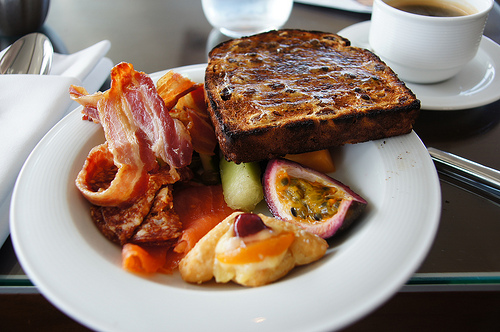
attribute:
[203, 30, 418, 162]
topping — fresh, burnt, buttered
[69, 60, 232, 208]
bacon — fresh, pink, strips, crispy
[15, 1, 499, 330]
breakfast — white, complimented, complete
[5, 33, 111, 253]
napkin — white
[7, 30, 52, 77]
spoon — metal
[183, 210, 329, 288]
crepe — sweet, fan shaped, pastry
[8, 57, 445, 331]
plate — white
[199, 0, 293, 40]
water — clear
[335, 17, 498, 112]
plate — white